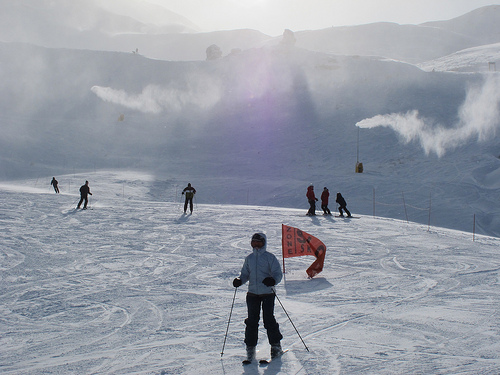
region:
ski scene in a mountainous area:
[2, 3, 494, 373]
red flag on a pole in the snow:
[277, 222, 330, 279]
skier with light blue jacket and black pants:
[219, 230, 313, 362]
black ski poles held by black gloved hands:
[217, 273, 317, 360]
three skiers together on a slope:
[300, 181, 362, 224]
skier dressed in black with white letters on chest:
[177, 182, 200, 220]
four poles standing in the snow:
[364, 180, 486, 247]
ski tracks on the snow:
[6, 229, 201, 368]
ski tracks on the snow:
[334, 237, 484, 362]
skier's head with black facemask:
[247, 230, 273, 254]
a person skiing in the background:
[47, 171, 62, 198]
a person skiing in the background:
[72, 172, 94, 213]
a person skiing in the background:
[177, 177, 200, 220]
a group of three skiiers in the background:
[301, 180, 358, 223]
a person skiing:
[227, 225, 289, 370]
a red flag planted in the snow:
[277, 219, 329, 284]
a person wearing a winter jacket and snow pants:
[232, 223, 289, 369]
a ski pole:
[217, 273, 242, 361]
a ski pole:
[265, 278, 316, 354]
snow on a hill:
[1, 190, 498, 372]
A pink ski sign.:
[278, 224, 332, 279]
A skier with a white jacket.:
[218, 231, 326, 373]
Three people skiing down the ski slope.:
[40, 171, 202, 234]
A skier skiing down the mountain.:
[155, 176, 218, 217]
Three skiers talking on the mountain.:
[299, 173, 366, 225]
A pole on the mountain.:
[340, 117, 370, 177]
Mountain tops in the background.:
[77, 1, 499, 104]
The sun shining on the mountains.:
[140, 5, 231, 68]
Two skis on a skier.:
[239, 341, 289, 373]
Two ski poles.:
[207, 276, 316, 365]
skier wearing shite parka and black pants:
[218, 225, 312, 374]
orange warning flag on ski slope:
[279, 215, 329, 290]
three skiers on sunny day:
[300, 175, 364, 226]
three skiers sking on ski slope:
[42, 167, 204, 223]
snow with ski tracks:
[13, 225, 197, 370]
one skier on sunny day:
[176, 180, 204, 222]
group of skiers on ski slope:
[41, 160, 361, 374]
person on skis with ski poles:
[210, 228, 315, 373]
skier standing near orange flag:
[221, 218, 333, 370]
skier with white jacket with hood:
[219, 228, 314, 372]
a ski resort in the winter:
[11, 11, 496, 368]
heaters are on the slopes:
[85, 73, 372, 179]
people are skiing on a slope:
[41, 168, 357, 369]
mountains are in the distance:
[9, 9, 499, 174]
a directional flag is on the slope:
[279, 220, 329, 288]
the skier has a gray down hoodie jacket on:
[240, 231, 282, 293]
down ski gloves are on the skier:
[228, 276, 278, 290]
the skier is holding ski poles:
[213, 277, 313, 362]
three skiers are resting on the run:
[298, 180, 360, 223]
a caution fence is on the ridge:
[355, 183, 499, 255]